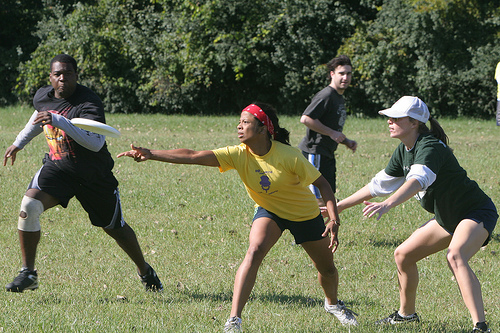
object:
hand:
[112, 147, 155, 163]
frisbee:
[69, 117, 125, 140]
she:
[317, 90, 499, 326]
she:
[113, 100, 371, 333]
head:
[46, 54, 81, 96]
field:
[1, 101, 500, 333]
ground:
[0, 108, 500, 333]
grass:
[0, 106, 500, 333]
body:
[301, 55, 359, 223]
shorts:
[248, 203, 330, 246]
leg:
[227, 212, 284, 327]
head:
[232, 102, 280, 146]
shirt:
[296, 85, 349, 153]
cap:
[374, 96, 439, 125]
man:
[3, 48, 164, 298]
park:
[22, 12, 499, 303]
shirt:
[211, 137, 326, 224]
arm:
[151, 147, 233, 167]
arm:
[10, 108, 47, 152]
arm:
[52, 109, 111, 153]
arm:
[292, 155, 336, 217]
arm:
[330, 168, 396, 211]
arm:
[382, 158, 438, 207]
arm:
[299, 96, 338, 135]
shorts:
[15, 158, 130, 231]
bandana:
[241, 103, 279, 135]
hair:
[253, 99, 289, 145]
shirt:
[27, 82, 114, 175]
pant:
[251, 207, 327, 244]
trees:
[18, 48, 57, 114]